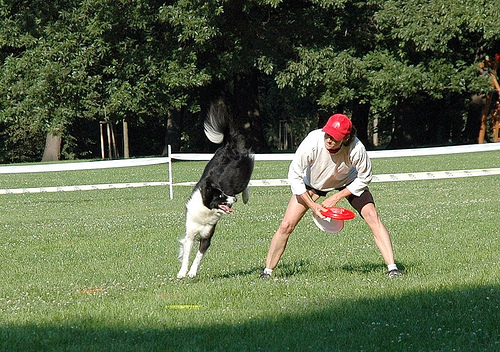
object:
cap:
[319, 112, 353, 143]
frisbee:
[319, 206, 357, 221]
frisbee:
[311, 212, 345, 234]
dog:
[172, 96, 256, 279]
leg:
[175, 228, 199, 279]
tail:
[203, 96, 245, 150]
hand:
[309, 203, 328, 221]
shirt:
[285, 127, 373, 198]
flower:
[390, 325, 397, 329]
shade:
[0, 281, 499, 352]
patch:
[162, 303, 205, 310]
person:
[256, 113, 403, 281]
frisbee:
[164, 304, 205, 310]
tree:
[0, 1, 499, 164]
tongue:
[216, 204, 235, 213]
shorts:
[303, 183, 376, 220]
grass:
[0, 149, 499, 352]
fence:
[0, 141, 499, 201]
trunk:
[40, 124, 62, 162]